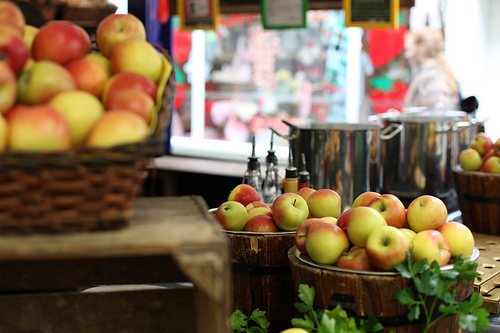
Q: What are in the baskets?
A: Apples.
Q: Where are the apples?
A: In the baskets.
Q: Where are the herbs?
A: In front of the baskets.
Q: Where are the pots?
A: Behind the baskets.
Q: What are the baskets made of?
A: Wood.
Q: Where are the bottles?
A: Behind the baskets of apples.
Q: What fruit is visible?
A: Apples.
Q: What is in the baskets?
A: Apples.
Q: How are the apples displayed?
A: In baskets.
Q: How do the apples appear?
A: Ripe.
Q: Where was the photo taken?
A: At a store.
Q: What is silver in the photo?
A: Pots.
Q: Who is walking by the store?
A: A female.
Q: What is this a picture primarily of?
A: Apples.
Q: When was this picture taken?
A: Daytime.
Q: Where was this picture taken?
A: Inside a store.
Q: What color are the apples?
A: Green and red.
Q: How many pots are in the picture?
A: 2.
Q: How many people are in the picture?
A: 1.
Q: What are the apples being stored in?
A: Wooden basket.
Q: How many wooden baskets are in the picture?
A: 4.